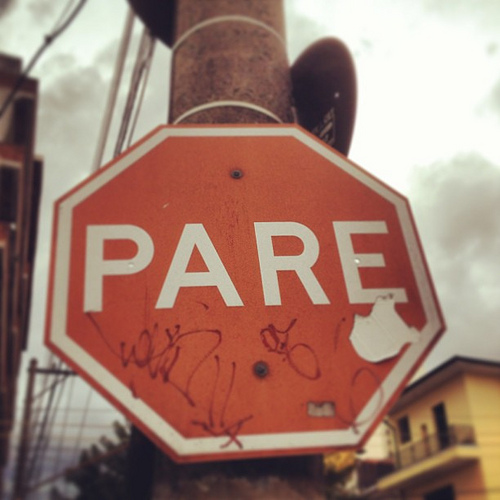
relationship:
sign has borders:
[55, 125, 445, 439] [64, 127, 260, 209]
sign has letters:
[55, 125, 445, 439] [83, 221, 400, 313]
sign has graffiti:
[55, 125, 445, 439] [122, 311, 343, 407]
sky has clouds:
[366, 29, 484, 193] [414, 148, 498, 273]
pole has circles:
[171, 2, 299, 123] [171, 13, 292, 50]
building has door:
[379, 357, 499, 486] [425, 400, 454, 447]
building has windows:
[379, 357, 499, 486] [397, 411, 415, 462]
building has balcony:
[379, 357, 499, 486] [375, 422, 478, 494]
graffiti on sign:
[122, 311, 343, 407] [55, 125, 445, 439]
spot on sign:
[346, 295, 427, 366] [55, 125, 445, 439]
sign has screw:
[55, 125, 445, 439] [227, 165, 246, 185]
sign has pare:
[55, 125, 445, 439] [86, 217, 407, 314]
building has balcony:
[379, 357, 499, 486] [383, 429, 475, 478]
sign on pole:
[288, 38, 361, 156] [171, 2, 299, 123]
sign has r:
[55, 125, 445, 439] [255, 221, 330, 313]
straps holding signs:
[166, 11, 302, 127] [127, 0, 364, 154]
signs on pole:
[127, 0, 364, 154] [171, 2, 299, 123]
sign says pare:
[55, 125, 445, 439] [86, 217, 407, 314]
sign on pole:
[55, 125, 445, 439] [171, 2, 299, 123]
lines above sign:
[23, 14, 157, 141] [55, 125, 445, 439]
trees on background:
[70, 427, 158, 496] [62, 418, 143, 488]